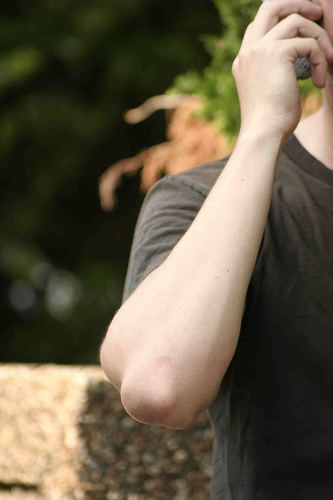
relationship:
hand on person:
[171, 7, 319, 318] [112, 59, 329, 494]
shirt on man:
[112, 133, 332, 305] [99, 0, 331, 500]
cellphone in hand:
[274, 4, 329, 82] [233, 2, 329, 124]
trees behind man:
[187, 52, 255, 144] [99, 0, 331, 500]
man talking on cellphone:
[221, 11, 314, 134] [257, 13, 329, 90]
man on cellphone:
[99, 0, 331, 500] [266, 21, 331, 83]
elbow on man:
[87, 290, 280, 409] [114, 58, 332, 495]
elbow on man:
[112, 352, 199, 436] [99, 0, 331, 500]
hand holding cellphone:
[230, 0, 332, 136] [294, 56, 310, 79]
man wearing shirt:
[99, 0, 331, 500] [136, 117, 330, 499]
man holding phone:
[99, 0, 331, 500] [267, 2, 322, 89]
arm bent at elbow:
[98, 1, 332, 431] [101, 292, 233, 428]